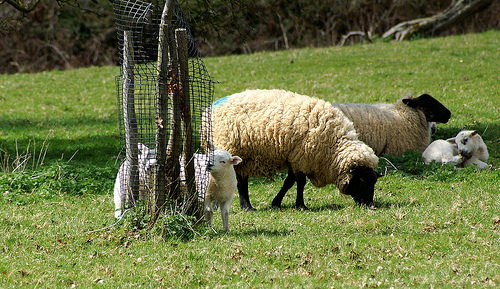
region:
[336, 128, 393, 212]
head of a sheep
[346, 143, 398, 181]
ear of a sheep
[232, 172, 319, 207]
legs of a sheep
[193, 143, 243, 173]
head of a sheep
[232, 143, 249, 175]
ear of a sheep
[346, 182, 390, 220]
mouth of a sheep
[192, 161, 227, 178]
mouth of a sheep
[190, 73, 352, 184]
body of a sheep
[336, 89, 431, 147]
body of a sheep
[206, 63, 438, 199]
sheep eating grass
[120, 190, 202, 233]
tall grass around a fence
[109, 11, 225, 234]
a black fence around a tree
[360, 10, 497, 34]
the trunk of a tree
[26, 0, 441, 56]
leaves on a tree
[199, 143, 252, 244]
a baby lamb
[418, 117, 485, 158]
a white lamb laying on the ground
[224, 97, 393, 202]
a white sheep with a black face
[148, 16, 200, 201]
logs in the ground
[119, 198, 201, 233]
weeds around a fence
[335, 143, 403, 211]
head of a sheep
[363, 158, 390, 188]
ear of a sheep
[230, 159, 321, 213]
legs of a sheep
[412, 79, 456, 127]
head of a sheep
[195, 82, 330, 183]
body of a sheep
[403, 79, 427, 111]
ear of a sheep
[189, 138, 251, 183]
head of a sheep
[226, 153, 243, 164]
ear of a sheep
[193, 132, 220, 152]
ear of a sheep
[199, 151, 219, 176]
nose of a sheep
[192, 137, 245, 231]
lamb by the wire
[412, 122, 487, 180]
Lamb laying in the grass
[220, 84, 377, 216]
sheep grazing in the field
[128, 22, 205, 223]
wooden posts with wire wrapped around them.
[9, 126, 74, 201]
weeds growing in the grass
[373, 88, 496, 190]
sheep laying down with the lamb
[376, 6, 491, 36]
dead tree fallen at the edge of the field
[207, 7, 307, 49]
bushes and shrubs at the edge of the field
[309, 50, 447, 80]
field of green grass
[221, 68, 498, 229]
sheep in a field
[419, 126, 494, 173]
white sheep in field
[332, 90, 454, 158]
white sheep in field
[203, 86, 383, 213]
white sheep in field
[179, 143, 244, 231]
white sheep in field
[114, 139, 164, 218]
white sheep in field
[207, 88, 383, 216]
sheep eats green grass